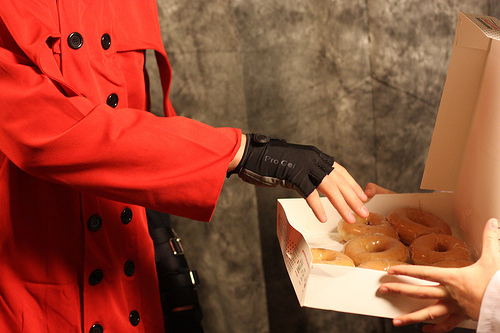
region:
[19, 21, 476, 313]
this person is grabbing donuts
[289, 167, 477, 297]
these donuts are glazed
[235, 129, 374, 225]
this lady wearing a fingerless glove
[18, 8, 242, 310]
this person has on a red coat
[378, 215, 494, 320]
this person is holding hte box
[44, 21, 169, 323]
black buttons on the box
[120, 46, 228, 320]
the woman is wearing a purse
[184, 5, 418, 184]
a brown wall in the background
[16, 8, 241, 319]
this looks like a fancy coat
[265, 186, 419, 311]
the donut box is white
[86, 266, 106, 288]
black button on a red coat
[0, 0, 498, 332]
a person reaching for glazed donuts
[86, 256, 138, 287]
two black buttons on a red coat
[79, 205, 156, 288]
four black buttons on a red coat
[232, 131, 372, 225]
a hand covered with a black glove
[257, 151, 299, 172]
text on a glove reading Pro Cel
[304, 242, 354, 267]
glazed donut in a box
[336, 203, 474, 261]
four glazed donuts in a box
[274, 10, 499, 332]
a person holding a box of glazed donuts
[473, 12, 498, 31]
krispy kreme logo on a donut box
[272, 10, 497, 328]
A cardboard box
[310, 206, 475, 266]
some donuts in a box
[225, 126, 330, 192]
A fingerless black glove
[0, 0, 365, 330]
A person in a red jacket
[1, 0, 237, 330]
A large red jacket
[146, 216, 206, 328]
A small handbag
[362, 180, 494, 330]
A person holding a box of donuts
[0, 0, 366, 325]
A person reaching for some donuts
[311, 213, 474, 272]
Some shiny glazed donuts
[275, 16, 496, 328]
A krispy kreme box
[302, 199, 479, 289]
Seven doughnuts in a box.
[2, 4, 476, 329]
A person just about to pick a doughnut.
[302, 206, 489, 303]
Brown doughnuts in a box.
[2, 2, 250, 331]
A person in a red long coat.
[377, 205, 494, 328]
A person's hand holding a box.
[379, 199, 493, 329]
A person holding a box of doughnuts.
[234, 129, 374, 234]
A glove on a person's hand.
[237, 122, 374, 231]
A black glove worn by a person.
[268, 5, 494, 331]
A box with doughnuts in it.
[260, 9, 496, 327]
A takeaway box with doughnuts in it.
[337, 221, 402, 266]
A dounut in a box.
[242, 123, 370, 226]
A black gloved hand.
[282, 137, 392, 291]
A hand going for a dounut.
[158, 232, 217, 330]
A black purse on a woman.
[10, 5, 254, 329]
A red trench coat on a woman.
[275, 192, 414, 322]
A big box of dounuts.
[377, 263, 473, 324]
Fingers holding a dounut box.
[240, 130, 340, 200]
A black, fingerless glove.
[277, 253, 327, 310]
A recite on the box of dounuts.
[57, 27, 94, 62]
A black button on a red trench coat.